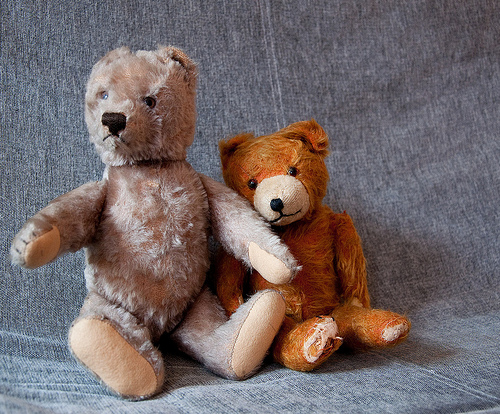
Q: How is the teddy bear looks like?
A: Brown.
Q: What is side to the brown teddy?
A: Reddish.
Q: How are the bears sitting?
A: Together.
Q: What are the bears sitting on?
A: Blue cloth.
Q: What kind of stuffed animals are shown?
A: Teddy bears.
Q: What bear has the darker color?
A: The bear on the right.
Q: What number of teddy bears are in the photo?
A: 2.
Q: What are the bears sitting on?
A: Cloth.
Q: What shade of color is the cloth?
A: Grayish.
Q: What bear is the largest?
A: The bear on the left.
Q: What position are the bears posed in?
A: Sitting.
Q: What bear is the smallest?
A: The bear on the right.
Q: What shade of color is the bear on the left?
A: Tan.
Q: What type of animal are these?
A: Bears.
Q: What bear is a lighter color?
A: The one on the left.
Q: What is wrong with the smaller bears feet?
A: They are ripping.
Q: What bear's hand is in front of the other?
A: The one on the left.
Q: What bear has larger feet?
A: The one on the left.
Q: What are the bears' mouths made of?
A: Black stitching.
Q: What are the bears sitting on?
A: A gray piece of furniture.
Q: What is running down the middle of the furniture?
A: Stitching.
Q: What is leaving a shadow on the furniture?
A: The teddy bears.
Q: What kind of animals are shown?
A: Stuffed bears.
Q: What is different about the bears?
A: Size.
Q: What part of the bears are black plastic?
A: Eyes.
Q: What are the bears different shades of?
A: Brown.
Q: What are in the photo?
A: Bears.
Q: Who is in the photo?
A: No one.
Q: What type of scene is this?
A: Indoor.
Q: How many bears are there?
A: Two.